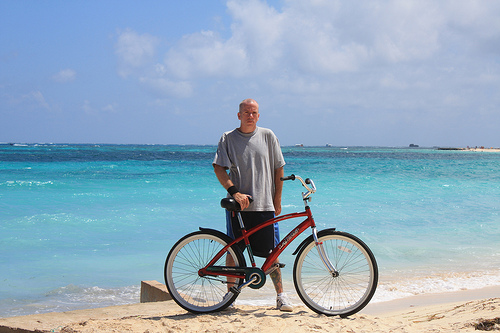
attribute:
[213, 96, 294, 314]
man — bald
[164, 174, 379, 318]
bike — red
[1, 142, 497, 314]
ocean — deep, blue, wavy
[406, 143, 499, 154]
island — behind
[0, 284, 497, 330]
beach — sandy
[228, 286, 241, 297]
pedal — chrome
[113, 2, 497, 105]
cloud — behind, white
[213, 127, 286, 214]
shirt — grey, gray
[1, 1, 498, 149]
sky — blue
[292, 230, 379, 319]
wheel — rubber, black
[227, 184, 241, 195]
armband — black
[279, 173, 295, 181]
handle — black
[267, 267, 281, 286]
tattoo — green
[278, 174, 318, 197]
bars — chrome